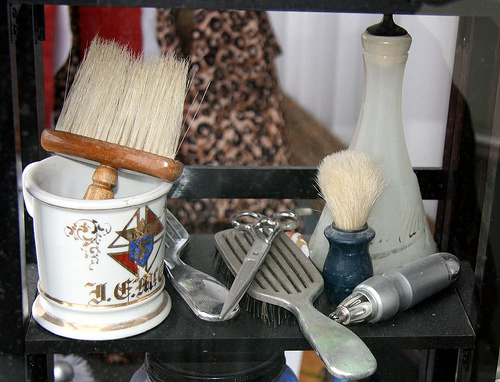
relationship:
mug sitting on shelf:
[18, 150, 186, 344] [28, 234, 475, 352]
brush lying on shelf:
[214, 217, 378, 380] [15, 260, 473, 351]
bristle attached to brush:
[276, 307, 280, 327] [208, 217, 334, 318]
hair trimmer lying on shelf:
[327, 252, 464, 327] [7, 214, 474, 357]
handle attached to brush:
[320, 228, 376, 300] [312, 148, 388, 304]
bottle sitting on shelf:
[306, 17, 439, 279] [28, 234, 475, 352]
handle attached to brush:
[80, 163, 118, 206] [33, 31, 252, 185]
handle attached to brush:
[292, 299, 384, 377] [214, 217, 378, 380]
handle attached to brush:
[320, 224, 377, 300] [316, 149, 390, 284]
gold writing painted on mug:
[37, 213, 170, 333] [21, 154, 173, 343]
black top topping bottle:
[363, 8, 411, 38] [308, 31, 439, 284]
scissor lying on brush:
[218, 211, 299, 321] [214, 217, 378, 380]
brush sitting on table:
[312, 148, 388, 304] [3, 160, 483, 373]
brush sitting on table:
[38, 28, 211, 201] [16, 221, 473, 353]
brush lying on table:
[205, 207, 380, 370] [3, 160, 483, 373]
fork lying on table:
[167, 217, 236, 317] [3, 160, 483, 373]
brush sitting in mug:
[38, 28, 211, 201] [21, 154, 173, 343]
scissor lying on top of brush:
[203, 186, 295, 328] [214, 217, 378, 380]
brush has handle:
[321, 148, 389, 302] [321, 220, 376, 297]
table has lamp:
[11, 247, 478, 380] [302, 13, 442, 292]